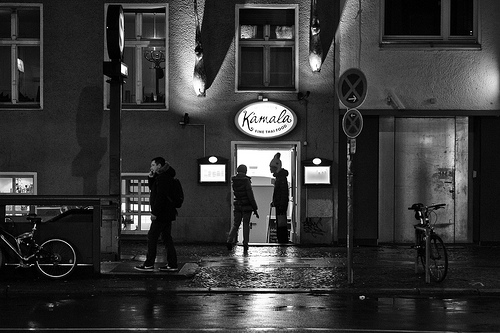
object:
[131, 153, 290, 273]
people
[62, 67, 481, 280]
restaurant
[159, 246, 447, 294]
sidewalk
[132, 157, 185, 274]
man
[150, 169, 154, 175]
cellphone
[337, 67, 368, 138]
signs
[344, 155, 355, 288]
pole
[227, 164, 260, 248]
women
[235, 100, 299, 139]
sign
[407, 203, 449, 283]
bike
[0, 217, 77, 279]
bicycle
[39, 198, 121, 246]
partition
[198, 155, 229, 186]
panels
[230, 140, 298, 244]
doorway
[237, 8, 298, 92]
window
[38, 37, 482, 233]
building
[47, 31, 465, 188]
store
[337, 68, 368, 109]
sign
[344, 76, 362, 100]
x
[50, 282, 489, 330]
street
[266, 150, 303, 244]
person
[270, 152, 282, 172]
cap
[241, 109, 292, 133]
letters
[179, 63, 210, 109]
light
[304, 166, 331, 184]
screen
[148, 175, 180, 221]
jacket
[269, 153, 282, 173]
hat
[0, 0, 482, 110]
windows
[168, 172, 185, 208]
backpack